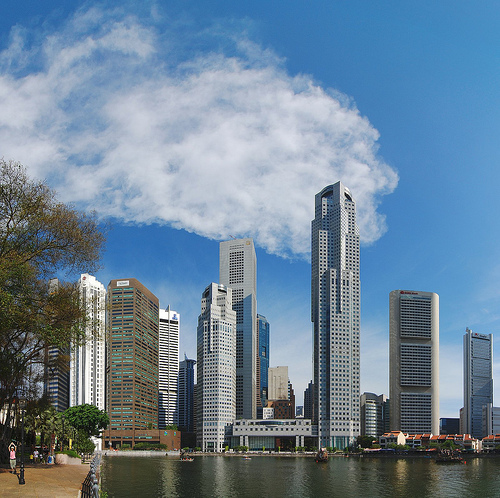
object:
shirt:
[9, 450, 16, 459]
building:
[304, 180, 361, 450]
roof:
[219, 234, 258, 259]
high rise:
[101, 278, 180, 450]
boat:
[436, 450, 463, 463]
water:
[149, 457, 367, 495]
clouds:
[0, 0, 398, 268]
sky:
[0, 0, 500, 190]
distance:
[268, 366, 315, 419]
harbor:
[101, 415, 499, 460]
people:
[7, 440, 18, 473]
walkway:
[0, 450, 97, 498]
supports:
[233, 419, 312, 454]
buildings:
[379, 430, 483, 453]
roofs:
[406, 433, 474, 441]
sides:
[324, 181, 353, 437]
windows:
[331, 315, 345, 337]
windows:
[112, 319, 134, 334]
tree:
[0, 154, 110, 444]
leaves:
[42, 324, 73, 346]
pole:
[17, 392, 27, 486]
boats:
[316, 447, 329, 461]